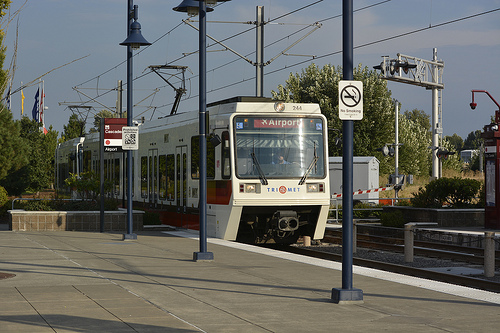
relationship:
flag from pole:
[31, 97, 39, 119] [33, 117, 43, 133]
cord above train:
[69, 3, 493, 113] [55, 99, 327, 251]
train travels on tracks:
[107, 92, 371, 257] [322, 215, 460, 290]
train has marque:
[30, 91, 341, 238] [249, 112, 319, 145]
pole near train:
[117, 1, 152, 238] [107, 92, 371, 257]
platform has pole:
[26, 219, 495, 327] [120, 25, 142, 242]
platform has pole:
[26, 219, 495, 327] [194, 11, 214, 266]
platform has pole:
[26, 219, 495, 327] [337, 4, 363, 299]